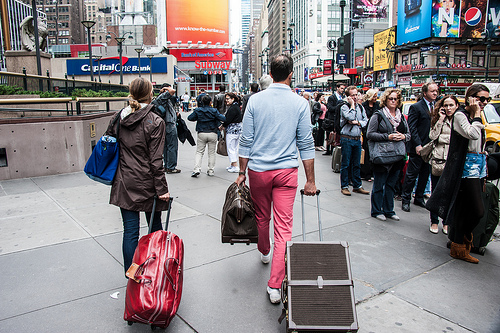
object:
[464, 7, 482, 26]
logo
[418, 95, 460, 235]
women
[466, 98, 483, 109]
cellphones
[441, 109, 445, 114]
cellphones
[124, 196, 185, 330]
luggage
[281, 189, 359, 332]
luggage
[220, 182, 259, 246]
luggage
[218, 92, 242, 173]
woman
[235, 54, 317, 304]
man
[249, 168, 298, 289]
pink pants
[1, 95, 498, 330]
sidewalk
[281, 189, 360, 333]
suitcase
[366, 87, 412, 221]
person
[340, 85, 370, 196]
person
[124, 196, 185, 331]
suit case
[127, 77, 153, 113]
hair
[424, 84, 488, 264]
woman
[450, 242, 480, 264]
boots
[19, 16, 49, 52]
statue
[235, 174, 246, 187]
hand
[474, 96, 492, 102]
glasses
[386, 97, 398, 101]
glasses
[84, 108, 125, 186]
bag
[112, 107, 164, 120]
shoulder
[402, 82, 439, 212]
person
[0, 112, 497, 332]
street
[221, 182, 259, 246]
suitcase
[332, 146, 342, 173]
suitcase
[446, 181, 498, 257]
suitcase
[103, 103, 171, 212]
coat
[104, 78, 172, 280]
lady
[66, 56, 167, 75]
sign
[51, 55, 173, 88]
wall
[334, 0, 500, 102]
building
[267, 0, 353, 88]
building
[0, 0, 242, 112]
building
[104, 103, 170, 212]
jacket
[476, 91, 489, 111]
face